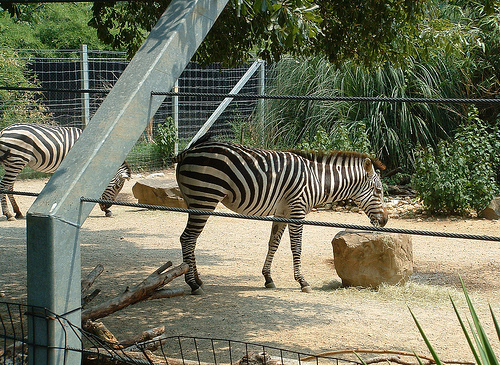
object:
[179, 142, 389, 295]
zebra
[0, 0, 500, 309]
zoo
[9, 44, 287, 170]
habitat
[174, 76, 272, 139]
fence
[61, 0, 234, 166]
boulder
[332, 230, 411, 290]
boulder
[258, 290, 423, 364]
dirt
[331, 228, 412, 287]
rock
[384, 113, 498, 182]
vegetation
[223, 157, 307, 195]
stripes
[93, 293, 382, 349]
ground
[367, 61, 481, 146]
bushes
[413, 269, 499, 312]
hay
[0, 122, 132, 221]
zebra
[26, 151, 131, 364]
beam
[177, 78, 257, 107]
wires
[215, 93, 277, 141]
sticks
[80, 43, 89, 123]
pole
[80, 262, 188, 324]
logs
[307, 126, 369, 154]
grass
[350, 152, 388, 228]
head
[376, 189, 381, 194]
eye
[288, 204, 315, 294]
leg